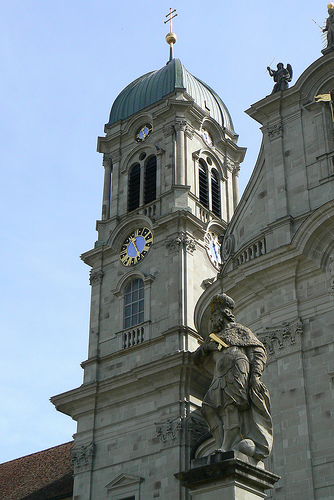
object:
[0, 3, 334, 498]
building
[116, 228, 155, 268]
clock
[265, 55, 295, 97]
statue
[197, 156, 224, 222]
window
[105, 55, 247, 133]
shingles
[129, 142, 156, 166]
triangle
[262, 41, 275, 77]
sword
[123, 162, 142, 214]
shutters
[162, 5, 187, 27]
vane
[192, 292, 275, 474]
carvings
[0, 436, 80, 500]
wall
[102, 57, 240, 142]
roof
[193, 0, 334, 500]
tower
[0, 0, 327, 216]
sky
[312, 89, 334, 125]
flag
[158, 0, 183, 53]
pole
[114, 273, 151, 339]
cross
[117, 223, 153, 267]
bells